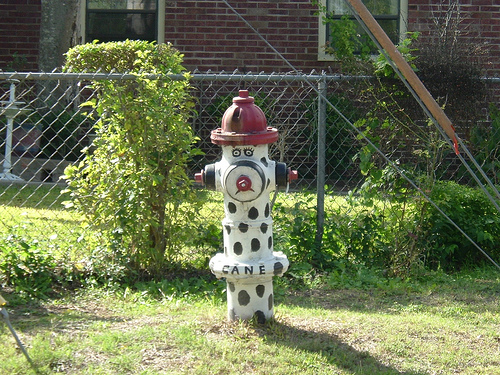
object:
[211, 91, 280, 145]
top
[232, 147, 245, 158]
eyes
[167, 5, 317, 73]
wall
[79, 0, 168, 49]
window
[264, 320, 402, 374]
shadow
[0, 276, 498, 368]
ground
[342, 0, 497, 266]
wires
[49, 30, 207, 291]
bush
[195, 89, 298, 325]
fire hydrant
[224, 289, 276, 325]
base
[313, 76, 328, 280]
pole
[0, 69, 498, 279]
fence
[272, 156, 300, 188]
nozzle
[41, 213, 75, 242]
light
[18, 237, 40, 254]
leaves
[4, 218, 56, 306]
bushes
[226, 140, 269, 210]
face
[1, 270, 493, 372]
grass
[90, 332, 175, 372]
clumps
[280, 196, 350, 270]
plants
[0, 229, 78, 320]
plants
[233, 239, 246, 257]
dalmation